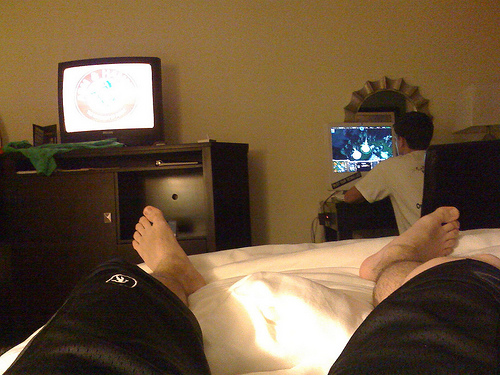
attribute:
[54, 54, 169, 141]
television — on, large, old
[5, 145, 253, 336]
cabinet — brown, wooden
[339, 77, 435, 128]
mirror — round, gold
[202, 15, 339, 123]
wall — yellow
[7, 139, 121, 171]
cloth — green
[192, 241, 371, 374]
sheet — white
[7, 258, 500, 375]
shorts — black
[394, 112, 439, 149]
boy's hair — short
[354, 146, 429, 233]
t shirt — white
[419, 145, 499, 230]
chair — black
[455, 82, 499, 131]
lampshade — square